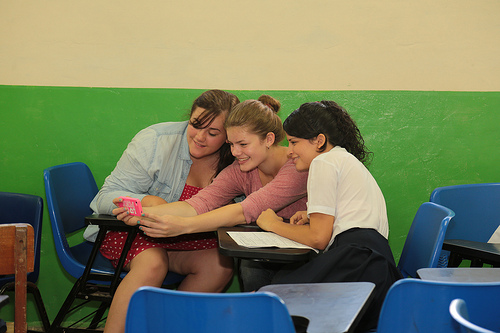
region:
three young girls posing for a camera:
[61, 77, 391, 299]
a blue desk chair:
[89, 275, 369, 330]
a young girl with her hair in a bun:
[219, 86, 286, 176]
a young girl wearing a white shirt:
[273, 73, 381, 253]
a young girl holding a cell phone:
[95, 94, 281, 255]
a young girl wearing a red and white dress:
[98, 86, 215, 271]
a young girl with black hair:
[275, 87, 376, 184]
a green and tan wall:
[1, 51, 436, 131]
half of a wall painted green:
[1, 28, 133, 189]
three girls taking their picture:
[33, 77, 386, 278]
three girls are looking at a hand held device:
[86, 92, 396, 312]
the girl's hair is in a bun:
[223, 92, 283, 174]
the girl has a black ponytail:
[286, 97, 376, 164]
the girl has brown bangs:
[185, 85, 233, 135]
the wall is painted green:
[8, 87, 498, 266]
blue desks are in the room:
[15, 150, 487, 331]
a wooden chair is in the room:
[4, 222, 39, 332]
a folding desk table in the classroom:
[238, 277, 380, 331]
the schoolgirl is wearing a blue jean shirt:
[83, 112, 195, 241]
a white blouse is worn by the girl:
[303, 145, 389, 242]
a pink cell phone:
[115, 195, 140, 220]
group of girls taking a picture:
[66, 80, 437, 255]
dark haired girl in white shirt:
[272, 81, 372, 221]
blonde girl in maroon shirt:
[212, 100, 309, 220]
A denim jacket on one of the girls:
[115, 130, 185, 185]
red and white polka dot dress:
[100, 175, 215, 272]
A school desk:
[221, 216, 307, 266]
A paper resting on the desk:
[231, 220, 311, 255]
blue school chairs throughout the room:
[30, 135, 495, 317]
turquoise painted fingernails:
[115, 188, 157, 230]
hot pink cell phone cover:
[110, 187, 147, 228]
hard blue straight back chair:
[49, 151, 108, 296]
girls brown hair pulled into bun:
[227, 94, 289, 146]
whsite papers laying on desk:
[223, 218, 319, 268]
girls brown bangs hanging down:
[180, 82, 235, 136]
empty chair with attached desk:
[128, 267, 356, 331]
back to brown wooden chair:
[2, 203, 49, 328]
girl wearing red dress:
[108, 159, 224, 257]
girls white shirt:
[304, 145, 393, 255]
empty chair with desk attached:
[416, 168, 497, 279]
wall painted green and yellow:
[379, 48, 498, 160]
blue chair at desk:
[410, 155, 497, 295]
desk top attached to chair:
[196, 264, 396, 331]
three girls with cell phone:
[99, 88, 395, 288]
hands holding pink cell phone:
[104, 191, 191, 253]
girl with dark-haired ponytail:
[281, 91, 420, 287]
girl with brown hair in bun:
[210, 87, 294, 179]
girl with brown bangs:
[174, 91, 243, 172]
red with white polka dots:
[97, 215, 242, 261]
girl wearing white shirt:
[276, 99, 405, 310]